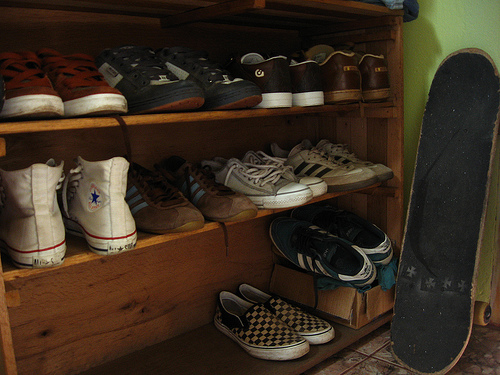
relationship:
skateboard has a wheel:
[392, 47, 497, 374] [474, 300, 492, 329]